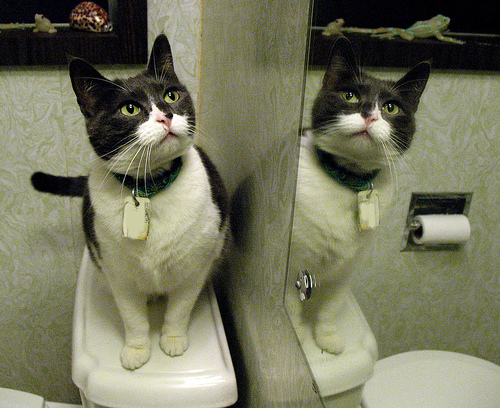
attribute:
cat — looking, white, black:
[70, 68, 233, 265]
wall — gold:
[230, 44, 275, 104]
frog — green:
[407, 16, 460, 44]